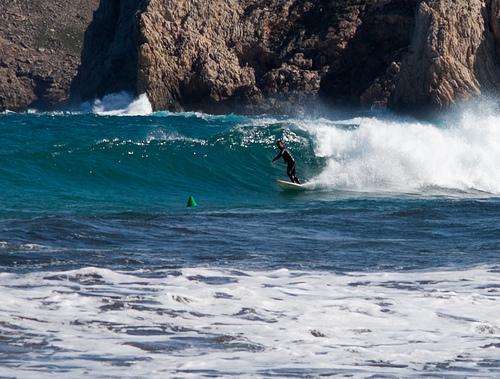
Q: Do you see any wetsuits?
A: Yes, there is a wetsuit.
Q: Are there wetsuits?
A: Yes, there is a wetsuit.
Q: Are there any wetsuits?
A: Yes, there is a wetsuit.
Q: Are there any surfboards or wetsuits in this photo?
A: Yes, there is a wetsuit.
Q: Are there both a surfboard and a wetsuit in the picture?
A: Yes, there are both a wetsuit and a surfboard.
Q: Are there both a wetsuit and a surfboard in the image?
A: Yes, there are both a wetsuit and a surfboard.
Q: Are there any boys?
A: No, there are no boys.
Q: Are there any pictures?
A: No, there are no pictures.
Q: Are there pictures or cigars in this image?
A: No, there are no pictures or cigars.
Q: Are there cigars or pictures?
A: No, there are no pictures or cigars.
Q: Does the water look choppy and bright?
A: No, the water is bright but calm.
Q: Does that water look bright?
A: Yes, the water is bright.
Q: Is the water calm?
A: Yes, the water is calm.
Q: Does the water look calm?
A: Yes, the water is calm.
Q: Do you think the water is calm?
A: Yes, the water is calm.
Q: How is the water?
A: The water is calm.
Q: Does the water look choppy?
A: No, the water is calm.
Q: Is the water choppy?
A: No, the water is calm.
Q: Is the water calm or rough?
A: The water is calm.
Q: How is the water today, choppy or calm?
A: The water is calm.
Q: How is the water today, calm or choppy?
A: The water is calm.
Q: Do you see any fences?
A: No, there are no fences.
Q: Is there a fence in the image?
A: No, there are no fences.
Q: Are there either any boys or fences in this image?
A: No, there are no fences or boys.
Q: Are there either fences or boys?
A: No, there are no fences or boys.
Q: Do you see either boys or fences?
A: No, there are no fences or boys.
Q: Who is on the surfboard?
A: The man is on the surfboard.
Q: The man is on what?
A: The man is on the surfboard.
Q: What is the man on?
A: The man is on the surfboard.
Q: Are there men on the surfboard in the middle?
A: Yes, there is a man on the surfboard.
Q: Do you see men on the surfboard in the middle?
A: Yes, there is a man on the surfboard.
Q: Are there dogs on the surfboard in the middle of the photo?
A: No, there is a man on the surfboard.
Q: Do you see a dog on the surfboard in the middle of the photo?
A: No, there is a man on the surfboard.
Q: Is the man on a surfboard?
A: Yes, the man is on a surfboard.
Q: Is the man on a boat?
A: No, the man is on a surfboard.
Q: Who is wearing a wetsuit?
A: The man is wearing a wetsuit.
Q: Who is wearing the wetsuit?
A: The man is wearing a wetsuit.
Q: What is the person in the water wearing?
A: The man is wearing a wetsuit.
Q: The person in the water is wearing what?
A: The man is wearing a wetsuit.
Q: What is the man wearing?
A: The man is wearing a wetsuit.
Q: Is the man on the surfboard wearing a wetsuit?
A: Yes, the man is wearing a wetsuit.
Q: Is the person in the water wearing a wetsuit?
A: Yes, the man is wearing a wetsuit.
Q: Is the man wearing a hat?
A: No, the man is wearing a wetsuit.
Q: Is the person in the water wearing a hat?
A: No, the man is wearing a wetsuit.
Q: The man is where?
A: The man is in the water.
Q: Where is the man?
A: The man is in the water.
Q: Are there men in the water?
A: Yes, there is a man in the water.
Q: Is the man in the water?
A: Yes, the man is in the water.